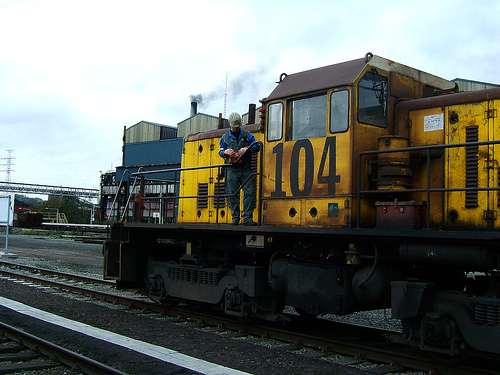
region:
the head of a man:
[210, 91, 265, 156]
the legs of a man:
[214, 166, 271, 224]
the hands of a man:
[210, 145, 253, 173]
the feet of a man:
[225, 208, 271, 239]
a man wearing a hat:
[196, 103, 281, 239]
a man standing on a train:
[181, 91, 307, 242]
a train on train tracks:
[80, 95, 397, 290]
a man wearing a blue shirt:
[210, 85, 274, 167]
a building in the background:
[159, 63, 274, 156]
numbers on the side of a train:
[237, 75, 447, 196]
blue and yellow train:
[134, 98, 498, 306]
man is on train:
[200, 84, 241, 245]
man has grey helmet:
[225, 105, 236, 139]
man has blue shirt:
[214, 123, 244, 180]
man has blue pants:
[202, 151, 259, 222]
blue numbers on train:
[247, 130, 359, 235]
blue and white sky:
[31, 33, 135, 103]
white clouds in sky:
[27, 15, 137, 102]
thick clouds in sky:
[27, 15, 151, 102]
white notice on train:
[415, 111, 462, 132]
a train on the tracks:
[24, 59, 495, 347]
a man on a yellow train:
[102, 93, 315, 225]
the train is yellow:
[122, 81, 481, 308]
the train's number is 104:
[256, 124, 349, 214]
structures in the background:
[2, 154, 112, 254]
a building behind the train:
[104, 94, 227, 135]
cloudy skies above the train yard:
[52, 17, 270, 91]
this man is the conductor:
[194, 107, 269, 223]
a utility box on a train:
[362, 183, 432, 236]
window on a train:
[247, 79, 390, 150]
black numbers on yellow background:
[270, 138, 347, 203]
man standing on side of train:
[215, 115, 265, 221]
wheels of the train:
[127, 241, 499, 365]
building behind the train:
[117, 98, 261, 138]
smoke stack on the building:
[180, 93, 204, 110]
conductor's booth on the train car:
[261, 63, 384, 224]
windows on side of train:
[262, 95, 347, 137]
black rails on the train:
[125, 139, 499, 231]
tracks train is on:
[10, 239, 412, 373]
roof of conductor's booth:
[267, 51, 392, 88]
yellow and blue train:
[104, 121, 479, 289]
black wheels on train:
[170, 233, 494, 348]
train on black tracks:
[5, 230, 163, 311]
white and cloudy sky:
[37, 31, 184, 142]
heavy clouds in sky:
[28, 33, 170, 68]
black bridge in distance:
[1, 183, 86, 210]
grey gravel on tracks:
[24, 268, 109, 322]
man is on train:
[212, 95, 264, 220]